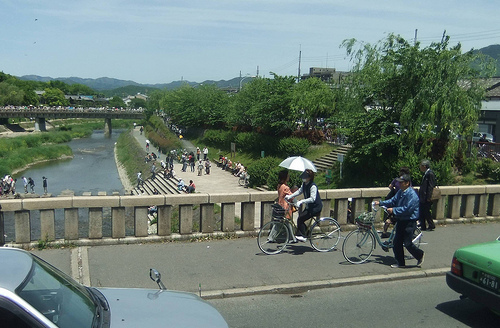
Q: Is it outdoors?
A: Yes, it is outdoors.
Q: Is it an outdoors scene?
A: Yes, it is outdoors.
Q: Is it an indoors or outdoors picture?
A: It is outdoors.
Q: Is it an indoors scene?
A: No, it is outdoors.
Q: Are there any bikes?
A: Yes, there is a bike.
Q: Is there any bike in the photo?
A: Yes, there is a bike.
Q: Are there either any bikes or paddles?
A: Yes, there is a bike.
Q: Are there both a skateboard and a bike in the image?
A: No, there is a bike but no skateboards.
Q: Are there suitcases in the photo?
A: No, there are no suitcases.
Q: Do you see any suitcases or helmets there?
A: No, there are no suitcases or helmets.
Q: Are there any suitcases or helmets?
A: No, there are no suitcases or helmets.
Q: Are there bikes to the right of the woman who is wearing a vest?
A: Yes, there is a bike to the right of the woman.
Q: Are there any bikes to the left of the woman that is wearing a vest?
A: No, the bike is to the right of the woman.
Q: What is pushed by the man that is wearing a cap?
A: The bike is pushed by the man.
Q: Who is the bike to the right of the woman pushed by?
A: The bike is pushed by the man.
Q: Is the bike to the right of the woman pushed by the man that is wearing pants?
A: Yes, the bike is pushed by the man.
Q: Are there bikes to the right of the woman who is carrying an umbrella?
A: Yes, there is a bike to the right of the woman.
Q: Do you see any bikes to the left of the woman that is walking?
A: No, the bike is to the right of the woman.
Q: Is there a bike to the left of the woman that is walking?
A: No, the bike is to the right of the woman.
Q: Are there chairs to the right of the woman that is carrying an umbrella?
A: No, there is a bike to the right of the woman.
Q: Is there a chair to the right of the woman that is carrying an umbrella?
A: No, there is a bike to the right of the woman.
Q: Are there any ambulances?
A: No, there are no ambulances.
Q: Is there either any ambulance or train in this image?
A: No, there are no ambulances or trains.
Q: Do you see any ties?
A: No, there are no ties.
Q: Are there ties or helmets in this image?
A: No, there are no ties or helmets.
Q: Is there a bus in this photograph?
A: No, there are no buses.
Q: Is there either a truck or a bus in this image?
A: No, there are no buses or trucks.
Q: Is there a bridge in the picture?
A: Yes, there is a bridge.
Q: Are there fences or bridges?
A: Yes, there is a bridge.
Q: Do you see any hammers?
A: No, there are no hammers.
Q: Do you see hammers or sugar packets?
A: No, there are no hammers or sugar packets.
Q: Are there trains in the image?
A: No, there are no trains.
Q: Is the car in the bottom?
A: Yes, the car is in the bottom of the image.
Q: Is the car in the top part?
A: No, the car is in the bottom of the image.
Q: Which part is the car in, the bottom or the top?
A: The car is in the bottom of the image.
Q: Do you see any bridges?
A: Yes, there is a bridge.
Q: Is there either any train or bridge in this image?
A: Yes, there is a bridge.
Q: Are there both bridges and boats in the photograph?
A: No, there is a bridge but no boats.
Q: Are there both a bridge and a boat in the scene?
A: No, there is a bridge but no boats.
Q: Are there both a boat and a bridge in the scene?
A: No, there is a bridge but no boats.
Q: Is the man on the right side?
A: Yes, the man is on the right of the image.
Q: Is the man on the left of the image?
A: No, the man is on the right of the image.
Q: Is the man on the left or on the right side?
A: The man is on the right of the image.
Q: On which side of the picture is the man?
A: The man is on the right of the image.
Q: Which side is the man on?
A: The man is on the right of the image.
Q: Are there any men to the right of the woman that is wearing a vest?
A: Yes, there is a man to the right of the woman.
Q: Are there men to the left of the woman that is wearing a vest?
A: No, the man is to the right of the woman.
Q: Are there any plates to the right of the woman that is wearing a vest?
A: No, there is a man to the right of the woman.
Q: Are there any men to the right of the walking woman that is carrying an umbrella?
A: Yes, there is a man to the right of the woman.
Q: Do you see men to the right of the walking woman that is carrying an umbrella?
A: Yes, there is a man to the right of the woman.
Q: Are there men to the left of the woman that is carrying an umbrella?
A: No, the man is to the right of the woman.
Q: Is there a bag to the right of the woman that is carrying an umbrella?
A: No, there is a man to the right of the woman.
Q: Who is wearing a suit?
A: The man is wearing a suit.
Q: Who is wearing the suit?
A: The man is wearing a suit.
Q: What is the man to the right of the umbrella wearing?
A: The man is wearing a suit.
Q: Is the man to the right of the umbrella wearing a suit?
A: Yes, the man is wearing a suit.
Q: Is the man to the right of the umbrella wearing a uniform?
A: No, the man is wearing a suit.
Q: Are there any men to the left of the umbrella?
A: No, the man is to the right of the umbrella.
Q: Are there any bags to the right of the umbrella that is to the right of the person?
A: No, there is a man to the right of the umbrella.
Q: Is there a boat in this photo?
A: No, there are no boats.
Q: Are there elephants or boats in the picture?
A: No, there are no boats or elephants.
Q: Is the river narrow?
A: Yes, the river is narrow.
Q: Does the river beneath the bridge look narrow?
A: Yes, the river is narrow.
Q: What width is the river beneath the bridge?
A: The river is narrow.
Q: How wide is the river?
A: The river is narrow.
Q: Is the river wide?
A: No, the river is narrow.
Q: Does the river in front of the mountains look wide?
A: No, the river is narrow.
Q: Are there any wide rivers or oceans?
A: No, there is a river but it is narrow.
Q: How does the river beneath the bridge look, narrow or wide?
A: The river is narrow.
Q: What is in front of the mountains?
A: The river is in front of the mountains.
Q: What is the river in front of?
A: The river is in front of the mountains.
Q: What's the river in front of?
A: The river is in front of the mountains.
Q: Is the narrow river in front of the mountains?
A: Yes, the river is in front of the mountains.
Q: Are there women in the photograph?
A: Yes, there is a woman.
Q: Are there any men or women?
A: Yes, there is a woman.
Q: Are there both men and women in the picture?
A: Yes, there are both a woman and a man.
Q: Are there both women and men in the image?
A: Yes, there are both a woman and a man.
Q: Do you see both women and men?
A: Yes, there are both a woman and a man.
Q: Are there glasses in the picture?
A: No, there are no glasses.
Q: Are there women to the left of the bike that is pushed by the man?
A: Yes, there is a woman to the left of the bike.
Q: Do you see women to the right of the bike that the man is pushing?
A: No, the woman is to the left of the bike.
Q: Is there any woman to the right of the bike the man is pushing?
A: No, the woman is to the left of the bike.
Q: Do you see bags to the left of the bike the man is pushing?
A: No, there is a woman to the left of the bike.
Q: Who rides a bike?
A: The woman rides a bike.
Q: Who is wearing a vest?
A: The woman is wearing a vest.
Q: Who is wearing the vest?
A: The woman is wearing a vest.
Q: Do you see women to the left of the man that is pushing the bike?
A: Yes, there is a woman to the left of the man.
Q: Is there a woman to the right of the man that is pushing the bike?
A: No, the woman is to the left of the man.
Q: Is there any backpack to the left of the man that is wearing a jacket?
A: No, there is a woman to the left of the man.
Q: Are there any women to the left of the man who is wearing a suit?
A: Yes, there is a woman to the left of the man.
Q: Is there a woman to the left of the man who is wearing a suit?
A: Yes, there is a woman to the left of the man.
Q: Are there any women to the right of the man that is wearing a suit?
A: No, the woman is to the left of the man.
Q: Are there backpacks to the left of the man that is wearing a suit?
A: No, there is a woman to the left of the man.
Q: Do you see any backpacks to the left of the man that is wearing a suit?
A: No, there is a woman to the left of the man.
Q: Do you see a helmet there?
A: No, there are no helmets.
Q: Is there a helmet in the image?
A: No, there are no helmets.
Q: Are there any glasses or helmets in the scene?
A: No, there are no helmets or glasses.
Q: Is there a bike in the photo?
A: Yes, there is a bike.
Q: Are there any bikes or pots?
A: Yes, there is a bike.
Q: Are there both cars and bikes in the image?
A: Yes, there are both a bike and a car.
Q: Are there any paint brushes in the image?
A: No, there are no paint brushes.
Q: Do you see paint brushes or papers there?
A: No, there are no paint brushes or papers.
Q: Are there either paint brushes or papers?
A: No, there are no paint brushes or papers.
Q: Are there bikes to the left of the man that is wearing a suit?
A: Yes, there is a bike to the left of the man.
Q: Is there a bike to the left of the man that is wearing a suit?
A: Yes, there is a bike to the left of the man.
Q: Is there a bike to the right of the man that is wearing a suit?
A: No, the bike is to the left of the man.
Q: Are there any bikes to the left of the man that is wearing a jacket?
A: Yes, there is a bike to the left of the man.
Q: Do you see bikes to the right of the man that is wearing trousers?
A: No, the bike is to the left of the man.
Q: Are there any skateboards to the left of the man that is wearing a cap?
A: No, there is a bike to the left of the man.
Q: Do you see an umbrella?
A: Yes, there is an umbrella.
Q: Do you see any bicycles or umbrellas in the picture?
A: Yes, there is an umbrella.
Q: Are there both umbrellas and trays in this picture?
A: No, there is an umbrella but no trays.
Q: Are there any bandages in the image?
A: No, there are no bandages.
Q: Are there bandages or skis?
A: No, there are no bandages or skis.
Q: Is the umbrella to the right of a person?
A: Yes, the umbrella is to the right of a person.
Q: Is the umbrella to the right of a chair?
A: No, the umbrella is to the right of a person.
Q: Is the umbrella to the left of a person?
A: No, the umbrella is to the right of a person.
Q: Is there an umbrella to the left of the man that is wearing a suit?
A: Yes, there is an umbrella to the left of the man.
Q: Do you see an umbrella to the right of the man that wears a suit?
A: No, the umbrella is to the left of the man.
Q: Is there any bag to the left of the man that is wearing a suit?
A: No, there is an umbrella to the left of the man.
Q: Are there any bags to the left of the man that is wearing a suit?
A: No, there is an umbrella to the left of the man.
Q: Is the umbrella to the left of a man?
A: Yes, the umbrella is to the left of a man.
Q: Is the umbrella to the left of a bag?
A: No, the umbrella is to the left of a man.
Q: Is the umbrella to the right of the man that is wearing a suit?
A: No, the umbrella is to the left of the man.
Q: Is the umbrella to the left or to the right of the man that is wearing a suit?
A: The umbrella is to the left of the man.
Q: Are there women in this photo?
A: Yes, there is a woman.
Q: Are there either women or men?
A: Yes, there is a woman.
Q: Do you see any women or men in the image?
A: Yes, there is a woman.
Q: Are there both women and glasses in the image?
A: No, there is a woman but no glasses.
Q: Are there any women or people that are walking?
A: Yes, the woman is walking.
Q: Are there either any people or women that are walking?
A: Yes, the woman is walking.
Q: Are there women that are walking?
A: Yes, there is a woman that is walking.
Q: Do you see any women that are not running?
A: Yes, there is a woman that is walking .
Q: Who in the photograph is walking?
A: The woman is walking.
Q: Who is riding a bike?
A: The woman is riding a bike.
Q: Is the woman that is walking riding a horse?
A: No, the woman is riding a bike.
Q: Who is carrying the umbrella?
A: The woman is carrying the umbrella.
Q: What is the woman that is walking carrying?
A: The woman is carrying an umbrella.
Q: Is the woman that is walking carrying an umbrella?
A: Yes, the woman is carrying an umbrella.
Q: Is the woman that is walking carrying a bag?
A: No, the woman is carrying an umbrella.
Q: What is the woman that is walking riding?
A: The woman is riding a bike.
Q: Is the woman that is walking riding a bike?
A: Yes, the woman is riding a bike.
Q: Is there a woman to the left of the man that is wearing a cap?
A: Yes, there is a woman to the left of the man.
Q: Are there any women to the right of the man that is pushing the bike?
A: No, the woman is to the left of the man.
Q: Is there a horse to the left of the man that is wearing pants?
A: No, there is a woman to the left of the man.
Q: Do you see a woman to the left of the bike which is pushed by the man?
A: Yes, there is a woman to the left of the bike.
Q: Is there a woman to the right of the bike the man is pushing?
A: No, the woman is to the left of the bike.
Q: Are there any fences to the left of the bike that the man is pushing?
A: No, there is a woman to the left of the bike.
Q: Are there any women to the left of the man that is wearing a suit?
A: Yes, there is a woman to the left of the man.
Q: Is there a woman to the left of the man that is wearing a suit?
A: Yes, there is a woman to the left of the man.